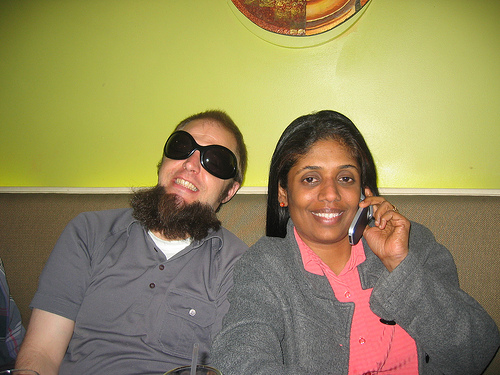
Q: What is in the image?
A: Two people.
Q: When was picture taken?
A: At night.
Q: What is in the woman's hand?
A: A cell phone.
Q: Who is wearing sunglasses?
A: The man.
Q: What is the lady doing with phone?
A: Talking.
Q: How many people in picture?
A: Two.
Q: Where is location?
A: Inside a building.